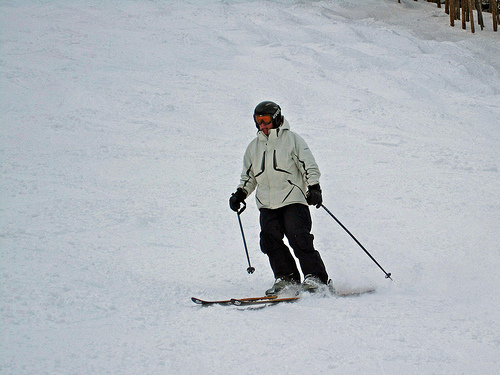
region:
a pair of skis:
[186, 282, 388, 312]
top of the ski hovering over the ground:
[227, 294, 297, 314]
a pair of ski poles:
[227, 201, 396, 290]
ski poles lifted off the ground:
[223, 198, 405, 292]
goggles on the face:
[250, 113, 277, 128]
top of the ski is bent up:
[185, 294, 204, 305]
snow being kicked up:
[276, 278, 355, 309]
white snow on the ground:
[0, 0, 499, 372]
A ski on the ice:
[237, 300, 286, 302]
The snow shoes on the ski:
[306, 279, 315, 286]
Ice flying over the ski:
[285, 287, 296, 293]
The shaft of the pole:
[242, 232, 244, 235]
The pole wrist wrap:
[240, 209, 243, 211]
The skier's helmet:
[259, 106, 275, 113]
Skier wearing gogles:
[255, 116, 267, 121]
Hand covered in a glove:
[308, 192, 321, 202]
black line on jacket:
[269, 150, 290, 177]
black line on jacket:
[252, 148, 267, 175]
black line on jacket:
[288, 177, 305, 200]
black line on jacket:
[285, 186, 296, 206]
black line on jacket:
[256, 190, 265, 207]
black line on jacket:
[244, 160, 254, 191]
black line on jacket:
[290, 151, 310, 186]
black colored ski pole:
[320, 203, 393, 285]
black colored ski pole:
[233, 197, 255, 276]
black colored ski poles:
[234, 206, 395, 282]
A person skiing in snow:
[178, 90, 406, 313]